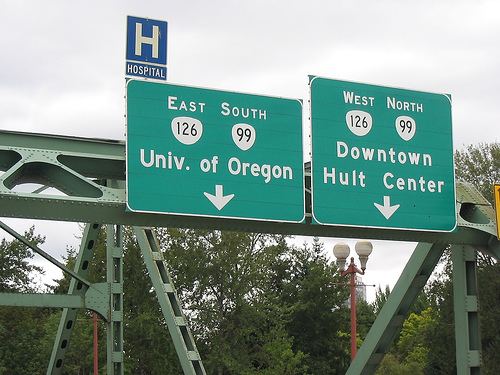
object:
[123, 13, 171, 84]
hospital sign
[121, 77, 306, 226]
freeway sign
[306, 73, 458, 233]
freeway sign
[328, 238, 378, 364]
lamp post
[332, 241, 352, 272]
dual lamps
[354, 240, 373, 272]
lamp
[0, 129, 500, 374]
trestle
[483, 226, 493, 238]
bents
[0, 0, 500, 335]
sky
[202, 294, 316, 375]
trees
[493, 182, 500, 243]
sign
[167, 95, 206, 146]
route 126 east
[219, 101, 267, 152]
route 99 south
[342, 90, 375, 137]
route 126 west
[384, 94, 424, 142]
route 99 north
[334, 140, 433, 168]
downtown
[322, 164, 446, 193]
hult center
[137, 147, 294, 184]
university of oregon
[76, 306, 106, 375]
lamp post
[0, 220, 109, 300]
sway brace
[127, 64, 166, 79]
word 'hospital'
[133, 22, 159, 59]
capital letter 'h'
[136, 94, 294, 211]
white lettering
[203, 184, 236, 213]
straight ahead arrow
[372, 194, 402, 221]
straight ahead arrow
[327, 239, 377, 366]
street lamp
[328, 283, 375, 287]
cross-bar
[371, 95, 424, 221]
route 99 north exit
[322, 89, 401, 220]
route 126 west exit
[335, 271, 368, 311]
building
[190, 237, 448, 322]
far distance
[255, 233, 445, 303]
cloud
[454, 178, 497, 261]
corner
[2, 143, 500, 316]
many bolts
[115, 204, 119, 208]
bolts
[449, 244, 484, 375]
supports